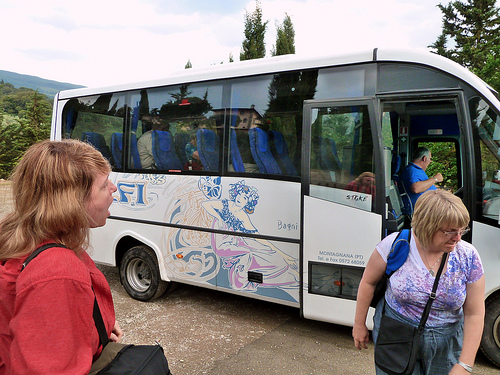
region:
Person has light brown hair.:
[37, 130, 59, 194]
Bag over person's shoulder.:
[75, 288, 139, 372]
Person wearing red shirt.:
[34, 271, 63, 346]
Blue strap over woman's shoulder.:
[374, 207, 402, 303]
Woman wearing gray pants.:
[410, 327, 442, 367]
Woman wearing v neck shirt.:
[414, 225, 494, 347]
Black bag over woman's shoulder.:
[370, 286, 402, 343]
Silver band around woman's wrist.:
[448, 353, 478, 372]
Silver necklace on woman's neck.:
[418, 251, 449, 288]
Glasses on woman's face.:
[429, 217, 496, 269]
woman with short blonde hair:
[351, 187, 488, 374]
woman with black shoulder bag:
[348, 187, 487, 369]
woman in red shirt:
[1, 137, 127, 374]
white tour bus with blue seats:
[51, 46, 498, 356]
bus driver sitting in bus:
[402, 146, 446, 191]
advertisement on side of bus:
[118, 174, 302, 291]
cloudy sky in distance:
[2, 1, 445, 55]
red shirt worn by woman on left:
[4, 237, 118, 374]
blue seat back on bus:
[244, 125, 281, 172]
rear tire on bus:
[117, 244, 169, 301]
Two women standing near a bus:
[8, 118, 498, 355]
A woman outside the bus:
[348, 164, 495, 372]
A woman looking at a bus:
[3, 120, 176, 374]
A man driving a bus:
[398, 131, 468, 213]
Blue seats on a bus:
[72, 103, 300, 169]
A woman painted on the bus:
[158, 168, 309, 304]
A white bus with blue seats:
[41, 49, 498, 349]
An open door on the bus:
[296, 85, 485, 345]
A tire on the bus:
[108, 238, 181, 303]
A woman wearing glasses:
[408, 178, 468, 267]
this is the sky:
[76, 15, 149, 45]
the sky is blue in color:
[201, 4, 228, 10]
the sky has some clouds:
[35, 20, 98, 50]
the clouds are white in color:
[50, 11, 101, 51]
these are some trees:
[236, 8, 296, 51]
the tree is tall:
[437, 7, 490, 60]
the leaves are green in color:
[246, 31, 260, 45]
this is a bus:
[36, 50, 493, 229]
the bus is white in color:
[117, 220, 132, 226]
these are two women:
[17, 139, 474, 364]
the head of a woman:
[408, 182, 472, 257]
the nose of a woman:
[448, 227, 463, 242]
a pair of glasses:
[433, 222, 475, 240]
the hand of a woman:
[347, 320, 377, 355]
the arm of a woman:
[351, 229, 399, 324]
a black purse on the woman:
[366, 307, 433, 372]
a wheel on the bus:
[114, 241, 174, 303]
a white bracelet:
[453, 356, 475, 373]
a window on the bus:
[217, 58, 377, 180]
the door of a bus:
[291, 85, 407, 332]